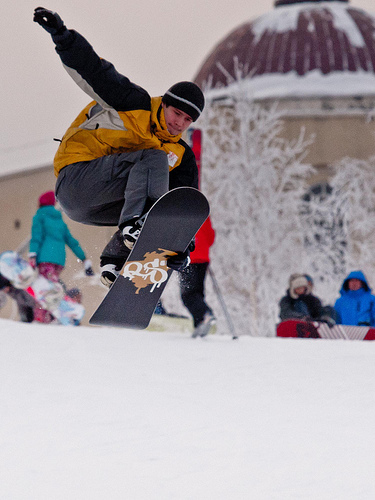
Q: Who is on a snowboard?
A: A man.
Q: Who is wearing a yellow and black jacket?
A: Snowboarder.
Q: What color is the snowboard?
A: Black.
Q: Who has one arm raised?
A: The snowboarder.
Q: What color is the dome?
A: Red.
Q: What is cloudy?
A: Sky.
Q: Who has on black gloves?
A: Man on snowboarder.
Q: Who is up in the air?
A: Snowboarder.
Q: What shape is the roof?
A: Dome.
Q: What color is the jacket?
A: Yellow.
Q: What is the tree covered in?
A: Snow.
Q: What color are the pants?
A: Gray.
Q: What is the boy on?
A: Snow board.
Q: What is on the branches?
A: Snow.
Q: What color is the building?
A: Beige.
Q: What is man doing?
A: A jump.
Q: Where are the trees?
A: In background.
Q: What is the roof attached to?
A: Building.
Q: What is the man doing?
A: Snowboarding.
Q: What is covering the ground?
A: Snow.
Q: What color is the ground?
A: White.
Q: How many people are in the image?
A: 4.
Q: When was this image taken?
A: In the winter.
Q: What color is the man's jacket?
A: Yellow and black.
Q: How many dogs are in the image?
A: 0.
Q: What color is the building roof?
A: Maroon.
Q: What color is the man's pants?
A: Gray.